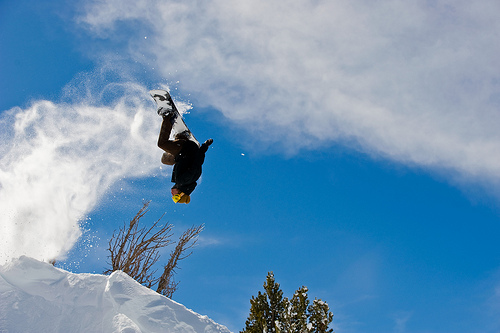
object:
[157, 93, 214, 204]
person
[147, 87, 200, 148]
snowboard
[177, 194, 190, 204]
hat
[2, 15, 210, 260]
snow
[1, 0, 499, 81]
air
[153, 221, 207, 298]
weed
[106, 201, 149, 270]
weed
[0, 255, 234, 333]
snowbank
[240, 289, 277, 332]
tree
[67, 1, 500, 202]
cloud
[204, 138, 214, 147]
glove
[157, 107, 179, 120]
foot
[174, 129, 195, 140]
foot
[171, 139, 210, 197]
jacket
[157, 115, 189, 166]
pants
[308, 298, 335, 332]
branch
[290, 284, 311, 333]
branch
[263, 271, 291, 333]
branch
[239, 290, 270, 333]
branch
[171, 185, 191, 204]
head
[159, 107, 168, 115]
snow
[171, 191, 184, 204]
goggles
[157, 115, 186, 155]
leg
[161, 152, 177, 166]
leg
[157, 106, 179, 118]
shoe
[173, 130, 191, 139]
shoe